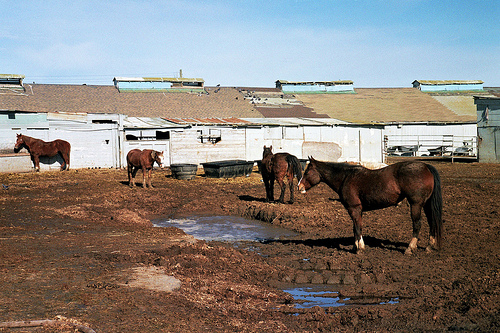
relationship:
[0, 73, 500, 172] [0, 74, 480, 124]
barn has roof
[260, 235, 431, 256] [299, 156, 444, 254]
shadow of horse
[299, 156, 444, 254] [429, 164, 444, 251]
horse has tail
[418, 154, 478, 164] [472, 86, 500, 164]
shadow on wall